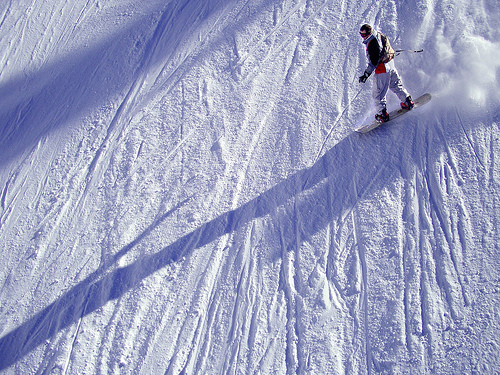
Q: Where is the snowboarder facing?
A: To the left.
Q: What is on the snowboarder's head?
A: A mask.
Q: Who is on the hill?
A: A snowboarder.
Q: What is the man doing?
A: Snowboarding.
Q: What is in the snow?
A: Lines from skiers and snowboarders.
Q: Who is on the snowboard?
A: A man.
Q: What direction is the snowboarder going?
A: To the left.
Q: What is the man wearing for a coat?
A: A black and gray coat.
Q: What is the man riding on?
A: A snowboard.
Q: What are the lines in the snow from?
A: People skiing and boarding down the hill.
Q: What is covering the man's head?
A: A ski mask.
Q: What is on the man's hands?
A: Ski gloves.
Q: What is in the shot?
A: The ground.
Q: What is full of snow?
A: The ground.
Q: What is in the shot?
A: Snow.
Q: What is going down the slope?
A: The snowboarder.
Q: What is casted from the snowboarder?
A: The shadow.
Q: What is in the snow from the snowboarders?
A: The tracks.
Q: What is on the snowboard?
A: The man.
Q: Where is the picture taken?
A: Ski slope.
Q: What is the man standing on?
A: Snowboard.